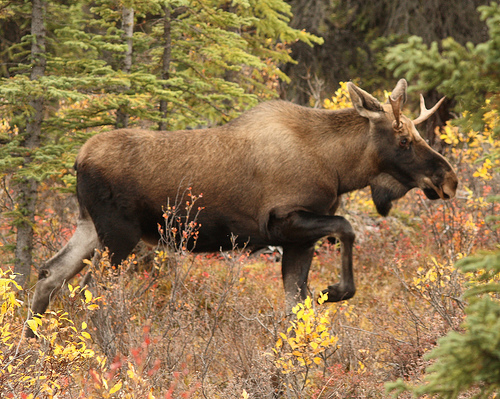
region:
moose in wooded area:
[10, 15, 491, 371]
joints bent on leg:
[286, 206, 363, 306]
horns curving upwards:
[380, 75, 445, 130]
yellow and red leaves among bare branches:
[0, 181, 405, 388]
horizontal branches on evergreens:
[10, 5, 320, 130]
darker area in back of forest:
[285, 0, 490, 90]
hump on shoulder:
[215, 85, 330, 137]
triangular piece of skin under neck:
[365, 160, 410, 221]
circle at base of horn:
[390, 111, 405, 132]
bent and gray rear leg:
[13, 197, 100, 362]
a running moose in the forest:
[31, 31, 453, 339]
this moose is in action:
[39, 35, 456, 305]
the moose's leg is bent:
[248, 199, 387, 334]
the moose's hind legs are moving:
[26, 142, 176, 397]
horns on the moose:
[385, 83, 460, 144]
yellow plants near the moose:
[10, 260, 353, 375]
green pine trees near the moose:
[26, 34, 261, 117]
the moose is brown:
[92, 67, 393, 223]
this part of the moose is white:
[27, 233, 113, 365]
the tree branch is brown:
[287, 4, 484, 124]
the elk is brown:
[10, 54, 470, 339]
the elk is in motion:
[0, 35, 455, 307]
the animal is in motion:
[12, 73, 477, 320]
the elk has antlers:
[363, 69, 460, 154]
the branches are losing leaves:
[112, 190, 252, 380]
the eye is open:
[390, 127, 419, 153]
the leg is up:
[253, 190, 388, 329]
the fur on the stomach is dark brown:
[125, 177, 261, 271]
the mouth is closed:
[410, 170, 452, 213]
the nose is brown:
[432, 157, 468, 201]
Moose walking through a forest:
[4, 5, 497, 397]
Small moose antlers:
[384, 86, 447, 131]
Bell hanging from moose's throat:
[363, 168, 415, 218]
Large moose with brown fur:
[19, 85, 459, 349]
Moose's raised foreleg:
[284, 210, 356, 303]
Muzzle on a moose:
[395, 145, 460, 202]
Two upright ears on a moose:
[344, 78, 410, 120]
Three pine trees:
[7, 0, 255, 297]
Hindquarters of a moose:
[21, 123, 181, 362]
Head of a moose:
[341, 72, 461, 213]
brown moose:
[78, 79, 463, 262]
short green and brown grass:
[41, 329, 111, 378]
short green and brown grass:
[123, 284, 195, 346]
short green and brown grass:
[204, 261, 244, 301]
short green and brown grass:
[187, 319, 242, 369]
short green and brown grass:
[259, 302, 317, 357]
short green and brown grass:
[327, 332, 378, 380]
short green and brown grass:
[427, 264, 463, 318]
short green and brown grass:
[368, 325, 427, 370]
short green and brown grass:
[385, 253, 420, 294]